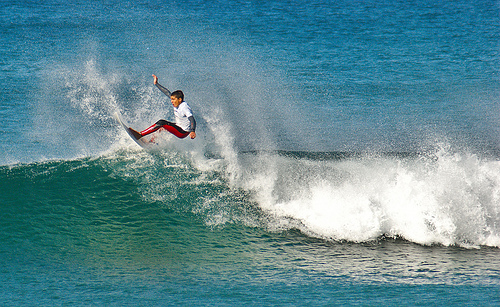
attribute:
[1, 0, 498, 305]
water — calm, blue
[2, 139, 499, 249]
wave — small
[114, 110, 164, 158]
board — white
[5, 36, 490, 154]
ocean — blue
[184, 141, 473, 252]
wave — large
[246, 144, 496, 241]
wave — white